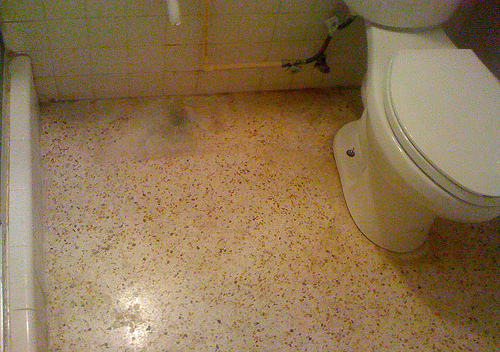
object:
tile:
[167, 45, 205, 71]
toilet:
[330, 0, 498, 253]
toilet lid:
[390, 44, 499, 197]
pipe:
[208, 58, 308, 73]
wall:
[0, 0, 499, 102]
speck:
[218, 247, 228, 255]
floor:
[33, 87, 499, 352]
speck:
[217, 245, 226, 254]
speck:
[167, 230, 177, 236]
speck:
[139, 217, 149, 228]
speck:
[253, 221, 260, 231]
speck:
[129, 240, 137, 249]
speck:
[88, 248, 98, 258]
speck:
[145, 325, 155, 333]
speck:
[203, 338, 213, 348]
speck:
[215, 318, 221, 326]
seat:
[383, 49, 499, 210]